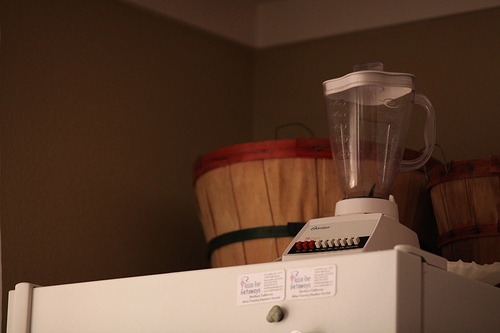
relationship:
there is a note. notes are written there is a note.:
[235, 272, 286, 305] [289, 262, 337, 298]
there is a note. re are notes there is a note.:
[235, 272, 286, 305] [235, 271, 287, 304]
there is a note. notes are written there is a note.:
[235, 271, 287, 304] [235, 272, 286, 305]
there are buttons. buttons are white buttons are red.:
[295, 235, 359, 250] [294, 239, 315, 250]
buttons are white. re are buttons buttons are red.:
[313, 236, 364, 251] [294, 239, 315, 250]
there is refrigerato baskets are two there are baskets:
[3, 245, 499, 331] [192, 123, 499, 266]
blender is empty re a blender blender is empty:
[271, 59, 435, 263] [271, 59, 435, 263]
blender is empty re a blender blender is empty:
[320, 59, 435, 200] [271, 59, 435, 263]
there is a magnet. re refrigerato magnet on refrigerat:
[265, 304, 285, 324] [3, 245, 499, 331]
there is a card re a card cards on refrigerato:
[235, 272, 286, 305] [3, 245, 499, 331]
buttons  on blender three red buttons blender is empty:
[293, 240, 302, 255] [271, 59, 435, 263]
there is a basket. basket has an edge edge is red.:
[190, 123, 444, 268] [186, 130, 446, 179]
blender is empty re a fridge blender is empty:
[271, 59, 435, 263] [271, 59, 435, 263]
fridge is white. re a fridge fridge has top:
[3, 245, 499, 331] [1, 250, 498, 301]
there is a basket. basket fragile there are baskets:
[190, 123, 444, 268] [421, 154, 499, 272]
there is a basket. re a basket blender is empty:
[190, 123, 444, 268] [271, 59, 435, 263]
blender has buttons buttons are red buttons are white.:
[280, 213, 424, 255] [313, 236, 364, 251]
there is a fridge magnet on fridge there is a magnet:
[3, 245, 499, 331] [265, 304, 285, 324]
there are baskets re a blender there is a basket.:
[192, 123, 499, 266] [190, 123, 439, 269]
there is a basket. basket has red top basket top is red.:
[190, 123, 444, 268] [186, 130, 446, 179]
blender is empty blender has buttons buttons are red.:
[271, 59, 435, 263] [294, 239, 315, 250]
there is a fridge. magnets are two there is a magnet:
[3, 245, 499, 331] [263, 304, 285, 324]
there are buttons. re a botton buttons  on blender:
[310, 237, 319, 249] [280, 213, 424, 255]